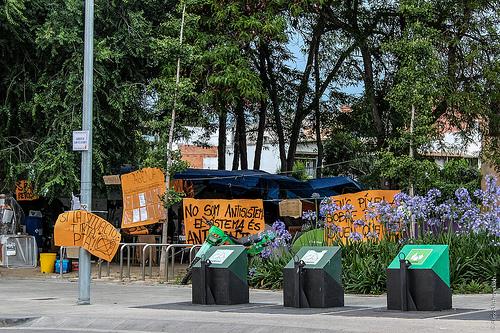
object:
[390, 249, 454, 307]
box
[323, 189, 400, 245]
sign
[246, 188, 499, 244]
flowers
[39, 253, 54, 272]
bucket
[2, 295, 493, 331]
ground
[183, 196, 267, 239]
sign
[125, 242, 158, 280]
rack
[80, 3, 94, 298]
pole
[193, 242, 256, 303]
bucket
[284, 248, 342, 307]
box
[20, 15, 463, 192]
trees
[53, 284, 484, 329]
road